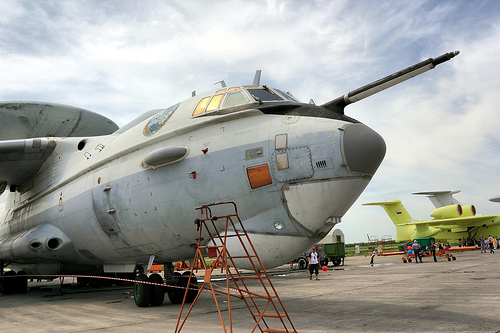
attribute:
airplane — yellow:
[381, 193, 490, 259]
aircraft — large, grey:
[4, 30, 480, 289]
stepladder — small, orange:
[180, 203, 280, 331]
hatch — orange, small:
[248, 162, 268, 186]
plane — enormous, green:
[362, 186, 498, 255]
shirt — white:
[304, 251, 320, 265]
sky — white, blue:
[2, 2, 497, 256]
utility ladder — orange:
[173, 195, 294, 331]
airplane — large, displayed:
[2, 45, 461, 306]